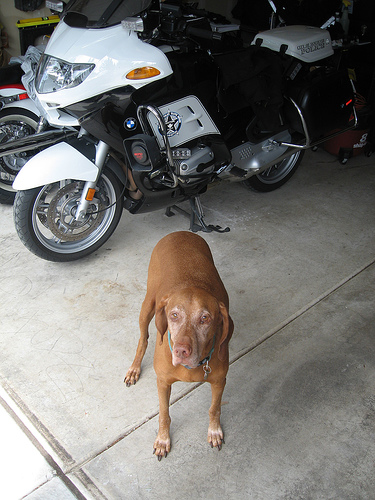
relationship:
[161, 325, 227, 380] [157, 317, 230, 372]
blue collar wrapped around neck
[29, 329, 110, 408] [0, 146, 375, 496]
thin marks in concrete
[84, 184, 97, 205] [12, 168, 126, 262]
orange reflector on wheel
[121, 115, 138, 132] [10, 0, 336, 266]
logo on motorcycle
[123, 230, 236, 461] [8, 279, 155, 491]
dog standing on concrete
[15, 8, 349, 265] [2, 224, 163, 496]
motorcycle parked on concrete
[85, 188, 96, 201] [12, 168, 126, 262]
orange reflector on wheel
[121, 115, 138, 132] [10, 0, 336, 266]
logo on side of motorcycle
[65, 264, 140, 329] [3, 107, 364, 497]
spot on ground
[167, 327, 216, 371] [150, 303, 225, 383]
blue collar around h neck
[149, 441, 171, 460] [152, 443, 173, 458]
nails are on paw